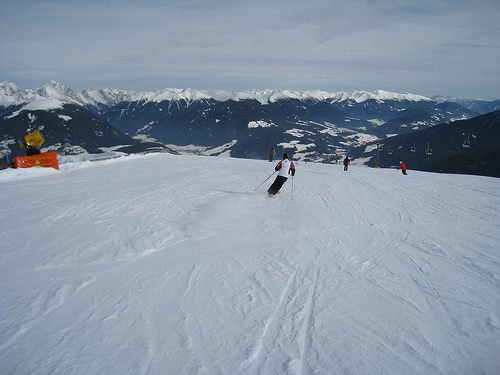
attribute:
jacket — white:
[260, 141, 299, 178]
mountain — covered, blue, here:
[180, 85, 434, 149]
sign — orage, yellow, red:
[16, 145, 67, 177]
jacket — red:
[394, 166, 415, 172]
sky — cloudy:
[166, 16, 380, 52]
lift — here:
[363, 121, 487, 165]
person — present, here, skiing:
[247, 145, 305, 194]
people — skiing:
[333, 145, 428, 175]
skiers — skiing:
[331, 156, 453, 185]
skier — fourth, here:
[249, 155, 308, 199]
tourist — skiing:
[254, 144, 309, 199]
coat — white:
[267, 148, 301, 182]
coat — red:
[396, 163, 408, 174]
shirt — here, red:
[395, 161, 415, 174]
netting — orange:
[24, 156, 61, 171]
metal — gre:
[410, 135, 463, 147]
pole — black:
[243, 155, 276, 192]